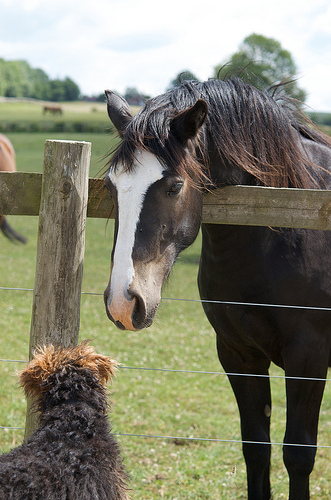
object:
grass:
[0, 134, 331, 499]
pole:
[23, 139, 92, 449]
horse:
[92, 70, 331, 498]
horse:
[0, 134, 27, 245]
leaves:
[212, 31, 309, 108]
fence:
[1, 138, 331, 500]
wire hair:
[0, 338, 133, 500]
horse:
[43, 105, 63, 116]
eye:
[104, 176, 113, 200]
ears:
[104, 90, 208, 142]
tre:
[210, 31, 309, 110]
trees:
[0, 57, 80, 103]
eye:
[166, 179, 185, 198]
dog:
[1, 338, 136, 498]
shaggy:
[0, 337, 132, 499]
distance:
[1, 59, 329, 98]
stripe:
[106, 146, 167, 301]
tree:
[213, 32, 310, 109]